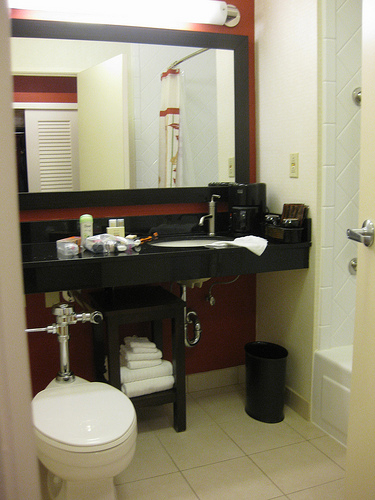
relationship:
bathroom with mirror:
[0, 1, 373, 499] [12, 18, 250, 211]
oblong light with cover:
[150, 4, 180, 10] [32, 2, 224, 23]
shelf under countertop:
[117, 320, 179, 403] [19, 210, 308, 293]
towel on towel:
[124, 335, 155, 349] [127, 345, 156, 352]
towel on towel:
[127, 345, 156, 352] [118, 343, 162, 358]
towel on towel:
[118, 343, 162, 358] [119, 358, 164, 365]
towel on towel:
[119, 358, 164, 365] [117, 362, 171, 377]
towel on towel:
[117, 362, 171, 377] [122, 375, 174, 396]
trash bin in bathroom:
[239, 335, 288, 431] [0, 1, 373, 499]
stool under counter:
[87, 282, 189, 431] [19, 215, 311, 288]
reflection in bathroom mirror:
[155, 67, 184, 190] [17, 19, 247, 208]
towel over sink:
[204, 234, 268, 254] [145, 236, 230, 246]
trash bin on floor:
[244, 341, 289, 425] [121, 375, 349, 498]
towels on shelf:
[102, 334, 174, 397] [88, 287, 192, 431]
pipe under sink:
[180, 285, 204, 351] [144, 193, 241, 255]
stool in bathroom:
[87, 282, 189, 431] [0, 1, 373, 499]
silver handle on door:
[350, 225, 373, 254] [363, 28, 374, 368]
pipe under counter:
[175, 283, 203, 349] [23, 211, 310, 291]